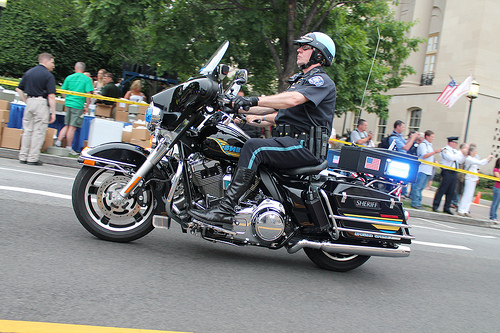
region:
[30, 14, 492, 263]
this cop might be leading a parade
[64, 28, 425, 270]
this cop is riding a motorcycle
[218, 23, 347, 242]
the officer looks serious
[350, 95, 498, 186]
these people are watching something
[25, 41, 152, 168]
these people look preoccupied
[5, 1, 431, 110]
trees near the street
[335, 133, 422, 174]
a garbage can with an American flag sticker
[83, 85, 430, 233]
the cop's motorcycle is black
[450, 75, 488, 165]
a street light above the people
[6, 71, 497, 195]
a yellow tape line to keep people back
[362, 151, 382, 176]
American flag on black box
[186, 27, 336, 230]
Police officer wearing black boot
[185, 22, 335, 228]
Police officer riding black motorcycle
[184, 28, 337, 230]
Police officer wearing helmet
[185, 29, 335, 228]
Police officer wearing black glove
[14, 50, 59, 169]
Man standing by yellow caution tape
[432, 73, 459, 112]
American flag near light post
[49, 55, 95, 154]
Man wearing green shirt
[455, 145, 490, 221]
Woman in white pants holding camera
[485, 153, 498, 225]
Woman wearing pink top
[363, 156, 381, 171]
American flag decal on the back of the motorcycle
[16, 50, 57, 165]
man in black shirt and khaki pants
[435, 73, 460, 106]
American flag on the side of the building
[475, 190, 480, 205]
orange safety cone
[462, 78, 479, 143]
tall post with light on the top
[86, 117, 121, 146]
large white cardboard box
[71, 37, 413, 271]
black motorcycle on the street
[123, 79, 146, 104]
blonde woman in white tank top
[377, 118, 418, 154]
man in blue shirt with a black backpack taking a picture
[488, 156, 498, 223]
woman in jeans and a pink shirt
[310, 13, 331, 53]
part of a helmet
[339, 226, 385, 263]
part of a metal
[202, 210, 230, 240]
edge of a boat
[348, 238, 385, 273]
part of a metal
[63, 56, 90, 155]
man in green shirt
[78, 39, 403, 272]
officer on a motorcycle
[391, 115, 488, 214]
group of people taking pictures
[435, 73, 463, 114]
american flag flying on the pole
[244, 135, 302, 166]
blue strip on officers pants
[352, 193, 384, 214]
word sheriff on side of motorcycle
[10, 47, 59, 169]
man in black shirt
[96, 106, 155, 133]
brown and white boxes on the sidewalk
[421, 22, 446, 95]
tan window on the building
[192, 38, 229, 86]
windshield on the motorcycle